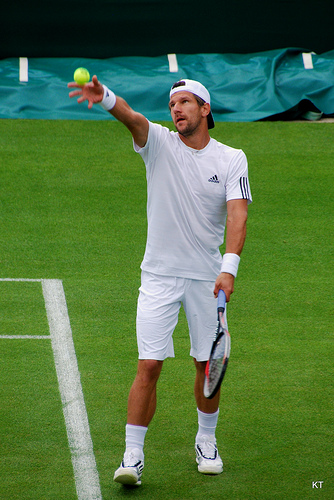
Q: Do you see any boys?
A: No, there are no boys.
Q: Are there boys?
A: No, there are no boys.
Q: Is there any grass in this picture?
A: Yes, there is grass.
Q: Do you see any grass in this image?
A: Yes, there is grass.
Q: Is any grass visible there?
A: Yes, there is grass.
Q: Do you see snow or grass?
A: Yes, there is grass.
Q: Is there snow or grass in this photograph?
A: Yes, there is grass.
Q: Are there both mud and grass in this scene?
A: No, there is grass but no mud.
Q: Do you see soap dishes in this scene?
A: No, there are no soap dishes.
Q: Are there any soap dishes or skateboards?
A: No, there are no soap dishes or skateboards.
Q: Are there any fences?
A: No, there are no fences.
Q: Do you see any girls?
A: No, there are no girls.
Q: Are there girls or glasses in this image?
A: No, there are no girls or glasses.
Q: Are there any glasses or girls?
A: No, there are no girls or glasses.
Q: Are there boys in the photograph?
A: No, there are no boys.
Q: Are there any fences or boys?
A: No, there are no boys or fences.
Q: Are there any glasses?
A: No, there are no glasses.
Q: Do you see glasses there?
A: No, there are no glasses.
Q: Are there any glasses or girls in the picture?
A: No, there are no glasses or girls.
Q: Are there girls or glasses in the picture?
A: No, there are no glasses or girls.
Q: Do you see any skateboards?
A: No, there are no skateboards.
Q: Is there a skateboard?
A: No, there are no skateboards.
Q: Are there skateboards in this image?
A: No, there are no skateboards.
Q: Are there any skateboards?
A: No, there are no skateboards.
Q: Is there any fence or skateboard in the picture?
A: No, there are no skateboards or fences.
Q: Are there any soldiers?
A: No, there are no soldiers.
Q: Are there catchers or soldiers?
A: No, there are no soldiers or catchers.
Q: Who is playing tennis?
A: The man is playing tennis.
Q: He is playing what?
A: The man is playing tennis.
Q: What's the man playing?
A: The man is playing tennis.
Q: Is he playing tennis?
A: Yes, the man is playing tennis.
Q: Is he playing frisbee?
A: No, the man is playing tennis.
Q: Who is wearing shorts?
A: The man is wearing shorts.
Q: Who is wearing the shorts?
A: The man is wearing shorts.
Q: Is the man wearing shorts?
A: Yes, the man is wearing shorts.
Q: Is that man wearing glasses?
A: No, the man is wearing shorts.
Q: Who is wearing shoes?
A: The man is wearing shoes.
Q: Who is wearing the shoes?
A: The man is wearing shoes.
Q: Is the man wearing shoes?
A: Yes, the man is wearing shoes.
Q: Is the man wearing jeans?
A: No, the man is wearing shoes.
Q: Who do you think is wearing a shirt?
A: The man is wearing a shirt.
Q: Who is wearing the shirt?
A: The man is wearing a shirt.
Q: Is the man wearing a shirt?
A: Yes, the man is wearing a shirt.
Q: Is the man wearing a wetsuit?
A: No, the man is wearing a shirt.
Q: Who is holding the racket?
A: The man is holding the tennis racket.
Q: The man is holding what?
A: The man is holding the racket.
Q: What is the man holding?
A: The man is holding the racket.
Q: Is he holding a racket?
A: Yes, the man is holding a racket.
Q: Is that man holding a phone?
A: No, the man is holding a racket.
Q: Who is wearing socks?
A: The man is wearing socks.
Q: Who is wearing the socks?
A: The man is wearing socks.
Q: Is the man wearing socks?
A: Yes, the man is wearing socks.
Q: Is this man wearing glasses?
A: No, the man is wearing socks.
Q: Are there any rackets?
A: Yes, there is a racket.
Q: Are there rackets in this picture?
A: Yes, there is a racket.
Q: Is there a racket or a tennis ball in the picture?
A: Yes, there is a racket.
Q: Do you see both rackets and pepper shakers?
A: No, there is a racket but no pepper shakers.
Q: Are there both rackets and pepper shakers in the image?
A: No, there is a racket but no pepper shakers.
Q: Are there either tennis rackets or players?
A: Yes, there is a tennis racket.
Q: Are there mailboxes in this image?
A: No, there are no mailboxes.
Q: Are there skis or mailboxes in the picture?
A: No, there are no mailboxes or skis.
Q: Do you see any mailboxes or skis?
A: No, there are no mailboxes or skis.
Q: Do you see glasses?
A: No, there are no glasses.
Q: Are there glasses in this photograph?
A: No, there are no glasses.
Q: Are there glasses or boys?
A: No, there are no glasses or boys.